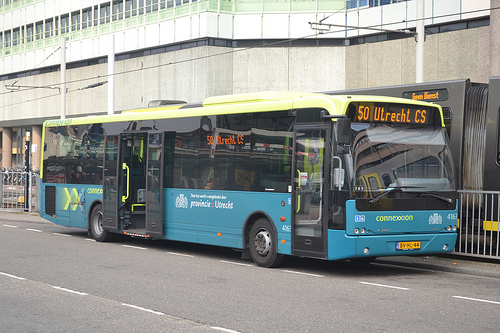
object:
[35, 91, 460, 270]
bus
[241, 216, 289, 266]
wheel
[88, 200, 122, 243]
wheel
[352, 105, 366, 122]
number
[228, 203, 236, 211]
letter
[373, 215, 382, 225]
letter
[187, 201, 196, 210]
letter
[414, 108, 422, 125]
letter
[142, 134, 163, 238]
door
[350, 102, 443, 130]
electric sign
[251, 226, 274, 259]
rim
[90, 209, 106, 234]
rim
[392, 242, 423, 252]
license plate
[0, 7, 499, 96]
electric wires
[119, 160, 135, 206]
handle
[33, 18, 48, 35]
window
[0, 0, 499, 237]
building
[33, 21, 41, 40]
window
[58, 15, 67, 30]
window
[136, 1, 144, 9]
window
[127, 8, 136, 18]
window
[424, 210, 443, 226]
logo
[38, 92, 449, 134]
roof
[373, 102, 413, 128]
utrecht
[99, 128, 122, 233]
rear doors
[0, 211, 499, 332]
street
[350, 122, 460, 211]
front window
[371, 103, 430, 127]
route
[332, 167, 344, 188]
mirror